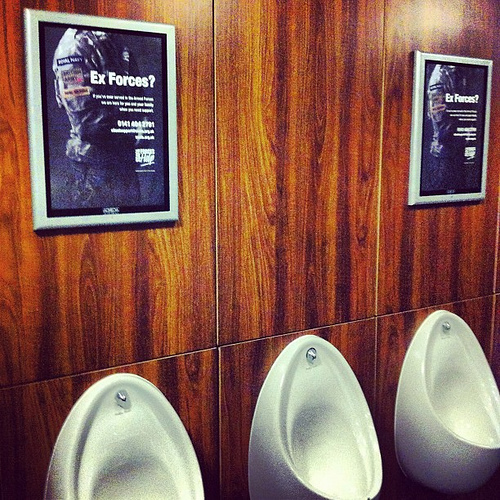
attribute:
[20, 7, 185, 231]
advertisement — framed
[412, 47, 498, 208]
picture — white 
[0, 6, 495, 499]
wall — brown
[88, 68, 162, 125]
words — white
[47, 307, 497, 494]
urinals — white, ceramic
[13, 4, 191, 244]
ad — framed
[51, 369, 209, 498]
urinal — white, shiny 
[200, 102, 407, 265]
panels — brown , wooden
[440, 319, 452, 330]
shiny metal — shiny , metal 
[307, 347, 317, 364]
shiny metal — shiny ,  metal 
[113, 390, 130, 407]
shiny metal — shiny ,  metal 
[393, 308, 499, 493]
urinal — white, shiny 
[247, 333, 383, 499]
urinal — white, shiny 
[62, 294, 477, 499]
urinals — white , round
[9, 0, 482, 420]
wall — wooden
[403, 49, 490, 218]
ad — white 